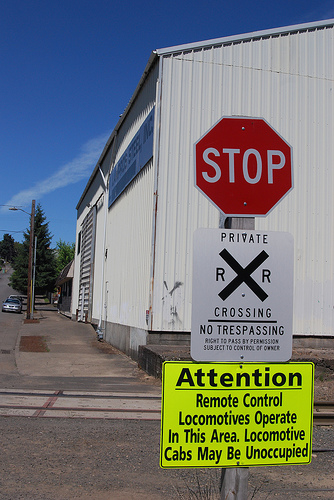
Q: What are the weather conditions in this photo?
A: It is cloudless.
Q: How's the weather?
A: It is cloudless.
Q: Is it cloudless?
A: Yes, it is cloudless.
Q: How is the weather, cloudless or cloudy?
A: It is cloudless.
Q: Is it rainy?
A: No, it is cloudless.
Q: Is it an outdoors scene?
A: Yes, it is outdoors.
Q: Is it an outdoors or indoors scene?
A: It is outdoors.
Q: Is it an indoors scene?
A: No, it is outdoors.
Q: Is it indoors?
A: No, it is outdoors.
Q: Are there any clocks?
A: No, there are no clocks.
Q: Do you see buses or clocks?
A: No, there are no clocks or buses.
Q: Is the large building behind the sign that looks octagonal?
A: Yes, the building is behind the sign.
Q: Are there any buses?
A: No, there are no buses.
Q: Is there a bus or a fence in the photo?
A: No, there are no buses or fences.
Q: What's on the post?
A: The sign is on the post.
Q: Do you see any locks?
A: No, there are no locks.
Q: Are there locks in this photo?
A: No, there are no locks.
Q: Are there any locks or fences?
A: No, there are no locks or fences.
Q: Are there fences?
A: No, there are no fences.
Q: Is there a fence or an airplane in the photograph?
A: No, there are no fences or airplanes.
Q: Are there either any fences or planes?
A: No, there are no fences or planes.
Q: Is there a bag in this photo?
A: No, there are no bags.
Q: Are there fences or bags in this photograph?
A: No, there are no bags or fences.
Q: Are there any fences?
A: No, there are no fences.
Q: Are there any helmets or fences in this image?
A: No, there are no fences or helmets.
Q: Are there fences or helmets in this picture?
A: No, there are no fences or helmets.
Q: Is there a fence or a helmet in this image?
A: No, there are no fences or helmets.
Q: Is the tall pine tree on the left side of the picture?
A: Yes, the pine tree is on the left of the image.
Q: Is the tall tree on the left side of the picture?
A: Yes, the pine tree is on the left of the image.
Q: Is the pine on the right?
A: No, the pine is on the left of the image.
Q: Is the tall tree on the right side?
A: No, the pine is on the left of the image.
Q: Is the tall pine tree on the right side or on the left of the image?
A: The pine is on the left of the image.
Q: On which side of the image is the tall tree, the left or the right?
A: The pine is on the left of the image.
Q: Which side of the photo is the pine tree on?
A: The pine tree is on the left of the image.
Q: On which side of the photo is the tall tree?
A: The pine tree is on the left of the image.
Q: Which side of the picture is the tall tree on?
A: The pine tree is on the left of the image.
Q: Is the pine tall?
A: Yes, the pine is tall.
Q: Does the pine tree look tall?
A: Yes, the pine tree is tall.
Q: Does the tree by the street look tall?
A: Yes, the pine tree is tall.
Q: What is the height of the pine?
A: The pine is tall.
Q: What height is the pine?
A: The pine is tall.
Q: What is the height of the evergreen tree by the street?
A: The pine is tall.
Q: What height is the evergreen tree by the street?
A: The pine is tall.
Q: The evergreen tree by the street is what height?
A: The pine is tall.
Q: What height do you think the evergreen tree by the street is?
A: The pine is tall.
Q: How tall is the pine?
A: The pine is tall.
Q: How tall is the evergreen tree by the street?
A: The pine is tall.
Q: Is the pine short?
A: No, the pine is tall.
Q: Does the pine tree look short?
A: No, the pine tree is tall.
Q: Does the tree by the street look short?
A: No, the pine tree is tall.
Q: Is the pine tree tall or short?
A: The pine tree is tall.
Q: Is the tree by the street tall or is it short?
A: The pine tree is tall.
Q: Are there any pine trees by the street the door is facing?
A: Yes, there is a pine tree by the street.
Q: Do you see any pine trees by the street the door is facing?
A: Yes, there is a pine tree by the street.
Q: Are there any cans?
A: No, there are no cans.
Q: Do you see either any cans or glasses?
A: No, there are no cans or glasses.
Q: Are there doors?
A: Yes, there is a door.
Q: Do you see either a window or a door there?
A: Yes, there is a door.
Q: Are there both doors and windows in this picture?
A: No, there is a door but no windows.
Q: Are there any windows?
A: No, there are no windows.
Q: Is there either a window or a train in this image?
A: No, there are no windows or trains.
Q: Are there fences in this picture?
A: No, there are no fences.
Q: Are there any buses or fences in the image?
A: No, there are no fences or buses.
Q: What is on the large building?
A: The sign is on the building.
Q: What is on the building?
A: The sign is on the building.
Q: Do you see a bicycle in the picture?
A: No, there are no bicycles.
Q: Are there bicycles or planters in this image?
A: No, there are no bicycles or planters.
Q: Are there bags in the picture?
A: No, there are no bags.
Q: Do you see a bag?
A: No, there are no bags.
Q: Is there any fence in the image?
A: No, there are no fences.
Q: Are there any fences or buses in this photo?
A: No, there are no fences or buses.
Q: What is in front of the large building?
A: The sign is in front of the building.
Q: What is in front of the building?
A: The sign is in front of the building.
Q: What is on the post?
A: The sign is on the post.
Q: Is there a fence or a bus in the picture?
A: No, there are no buses or fences.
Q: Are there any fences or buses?
A: No, there are no buses or fences.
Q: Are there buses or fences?
A: No, there are no buses or fences.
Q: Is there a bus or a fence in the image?
A: No, there are no buses or fences.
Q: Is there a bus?
A: No, there are no buses.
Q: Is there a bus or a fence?
A: No, there are no buses or fences.